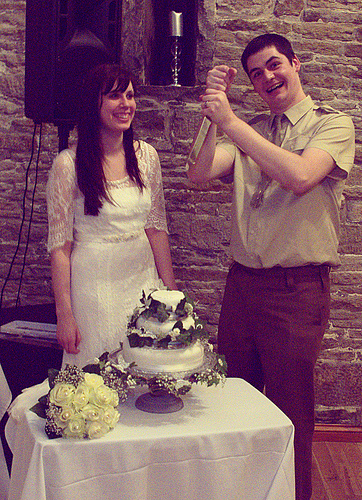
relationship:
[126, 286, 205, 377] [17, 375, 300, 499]
cake on a table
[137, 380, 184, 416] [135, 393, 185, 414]
pedestal has a base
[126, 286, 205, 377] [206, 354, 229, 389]
cake has leaves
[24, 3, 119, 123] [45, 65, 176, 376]
speaker behind bride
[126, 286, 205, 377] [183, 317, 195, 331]
cake has flowers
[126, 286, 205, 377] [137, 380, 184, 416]
cake on a pedestal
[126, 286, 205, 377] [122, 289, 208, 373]
cake has three tiers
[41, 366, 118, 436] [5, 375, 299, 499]
bouquet on a table cloth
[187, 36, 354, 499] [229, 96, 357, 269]
man has on a shirt